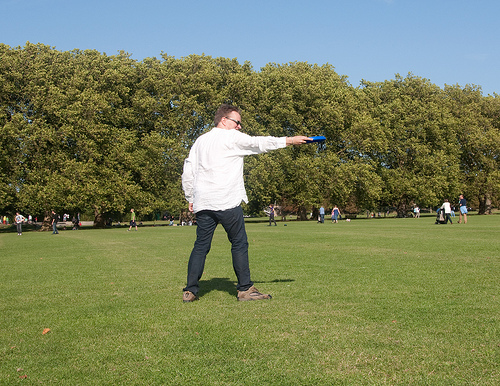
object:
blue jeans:
[182, 203, 254, 296]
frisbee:
[304, 132, 327, 153]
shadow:
[184, 277, 296, 301]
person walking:
[332, 204, 341, 223]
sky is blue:
[0, 0, 500, 96]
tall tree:
[17, 39, 100, 231]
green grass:
[0, 209, 499, 385]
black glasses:
[225, 116, 243, 127]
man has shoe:
[236, 284, 273, 303]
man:
[180, 102, 315, 304]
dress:
[333, 207, 340, 220]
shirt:
[180, 126, 288, 215]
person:
[125, 208, 138, 232]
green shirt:
[130, 212, 137, 221]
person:
[51, 210, 59, 234]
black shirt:
[51, 214, 59, 223]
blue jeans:
[52, 222, 59, 233]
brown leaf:
[41, 328, 50, 336]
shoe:
[182, 289, 200, 302]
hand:
[286, 135, 314, 146]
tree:
[0, 41, 500, 232]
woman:
[332, 204, 341, 223]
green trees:
[461, 90, 500, 217]